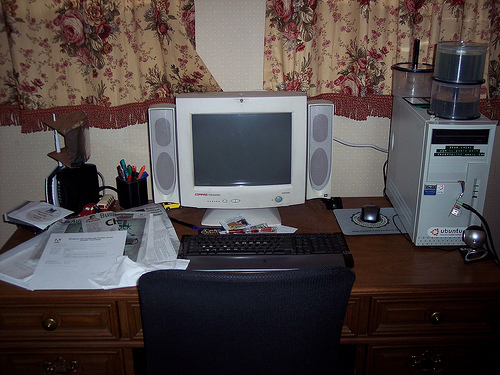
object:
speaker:
[304, 98, 334, 201]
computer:
[174, 88, 307, 226]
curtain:
[260, 0, 496, 105]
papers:
[2, 207, 187, 307]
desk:
[3, 183, 498, 360]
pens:
[112, 159, 164, 210]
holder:
[116, 170, 148, 207]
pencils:
[117, 155, 148, 178]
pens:
[114, 157, 149, 177]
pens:
[107, 156, 147, 181]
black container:
[114, 172, 149, 209]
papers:
[24, 221, 139, 299]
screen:
[175, 92, 307, 207]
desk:
[4, 247, 498, 357]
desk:
[356, 237, 421, 278]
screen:
[221, 123, 278, 158]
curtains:
[2, 2, 499, 142]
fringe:
[1, 97, 193, 132]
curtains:
[0, 0, 227, 128]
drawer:
[2, 297, 127, 349]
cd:
[419, 33, 491, 113]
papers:
[3, 199, 302, 288]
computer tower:
[378, 83, 498, 255]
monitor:
[246, 86, 311, 163]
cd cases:
[389, 30, 489, 123]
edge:
[109, 117, 127, 130]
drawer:
[3, 300, 116, 336]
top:
[376, 257, 420, 287]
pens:
[110, 157, 151, 188]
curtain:
[6, 18, 169, 110]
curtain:
[265, 15, 382, 82]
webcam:
[458, 225, 488, 262]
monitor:
[115, 66, 368, 236]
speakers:
[136, 107, 231, 218]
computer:
[156, 103, 308, 188]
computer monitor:
[172, 90, 307, 212]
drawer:
[356, 288, 492, 343]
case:
[429, 69, 483, 119]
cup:
[111, 170, 149, 206]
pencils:
[112, 159, 146, 195]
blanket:
[1, 3, 224, 129]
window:
[2, 1, 223, 135]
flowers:
[3, 3, 491, 115]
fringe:
[2, 92, 498, 130]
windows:
[4, 2, 496, 131]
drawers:
[0, 296, 498, 372]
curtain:
[2, 0, 226, 136]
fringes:
[0, 80, 202, 134]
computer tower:
[383, 97, 497, 252]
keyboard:
[175, 229, 353, 269]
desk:
[1, 196, 499, 372]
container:
[110, 168, 158, 219]